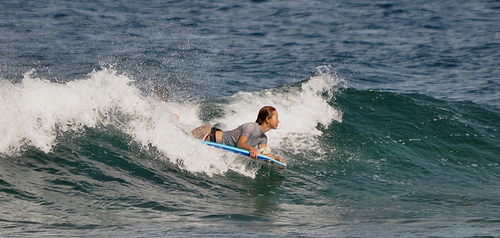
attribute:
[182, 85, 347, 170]
man — light skinned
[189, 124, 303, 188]
surfboard — blue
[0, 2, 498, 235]
water — white, dark green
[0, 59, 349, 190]
wave — crest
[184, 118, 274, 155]
suit — wet, gray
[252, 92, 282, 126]
hair — wet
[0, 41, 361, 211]
water — spraying up in air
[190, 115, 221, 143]
pants — tan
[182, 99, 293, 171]
woman — surfing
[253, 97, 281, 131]
hair — short, brown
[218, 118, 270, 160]
shirt — wet, gray, short, sleeved, T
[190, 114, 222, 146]
bottom — bikini, black, wet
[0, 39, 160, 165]
spray — sea, white, section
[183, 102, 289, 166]
woman — one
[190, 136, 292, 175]
surfboard — blue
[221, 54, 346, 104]
wave — white, capped, ocean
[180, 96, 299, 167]
surfer — one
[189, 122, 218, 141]
shorts — brown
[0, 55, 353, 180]
water — white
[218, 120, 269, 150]
shirt — gray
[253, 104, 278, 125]
hair — wet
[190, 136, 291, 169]
board — blue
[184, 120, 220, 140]
shorts — tan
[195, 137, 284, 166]
boogie board — blue